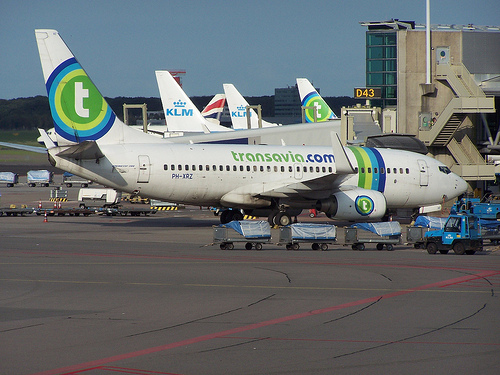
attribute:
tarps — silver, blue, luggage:
[194, 202, 471, 286]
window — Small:
[146, 146, 210, 181]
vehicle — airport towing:
[419, 212, 482, 258]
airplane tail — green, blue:
[31, 23, 140, 151]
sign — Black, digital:
[354, 86, 378, 98]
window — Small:
[212, 162, 217, 174]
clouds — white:
[84, 26, 177, 93]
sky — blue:
[0, 4, 500, 98]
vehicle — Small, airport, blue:
[423, 204, 490, 275]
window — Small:
[143, 146, 360, 187]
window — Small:
[309, 165, 315, 174]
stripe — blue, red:
[201, 95, 226, 113]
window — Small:
[155, 158, 167, 170]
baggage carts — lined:
[199, 215, 459, 250]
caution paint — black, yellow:
[47, 194, 69, 203]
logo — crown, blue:
[172, 97, 186, 108]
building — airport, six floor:
[354, 18, 488, 191]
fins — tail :
[8, 29, 338, 129]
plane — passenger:
[27, 23, 474, 233]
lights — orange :
[353, 88, 383, 97]